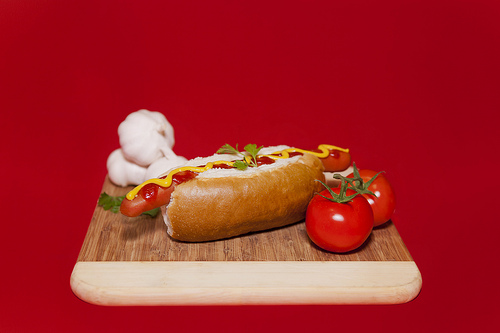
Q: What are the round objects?
A: Tomatoes.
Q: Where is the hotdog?
A: On tray.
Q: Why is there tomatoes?
A: For art.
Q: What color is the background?
A: Red.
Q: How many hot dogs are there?
A: One.